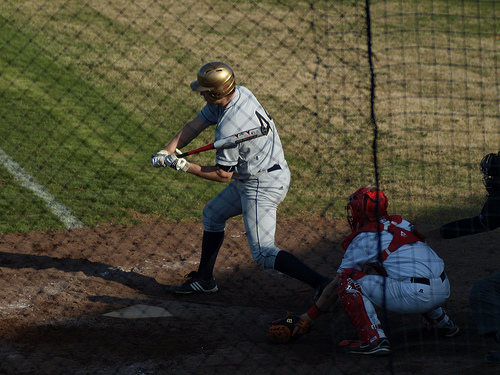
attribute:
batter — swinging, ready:
[172, 55, 330, 298]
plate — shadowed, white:
[105, 300, 178, 323]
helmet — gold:
[187, 63, 237, 95]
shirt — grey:
[208, 87, 282, 168]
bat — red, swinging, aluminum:
[173, 123, 273, 157]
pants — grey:
[207, 170, 288, 259]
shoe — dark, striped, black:
[169, 268, 221, 295]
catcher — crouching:
[313, 187, 460, 345]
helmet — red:
[358, 181, 385, 220]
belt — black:
[405, 271, 453, 285]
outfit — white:
[343, 229, 447, 317]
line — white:
[3, 141, 87, 233]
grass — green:
[4, 8, 495, 224]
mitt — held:
[264, 308, 307, 340]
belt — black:
[260, 161, 285, 174]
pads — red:
[338, 277, 380, 341]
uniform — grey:
[196, 95, 302, 262]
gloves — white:
[155, 146, 184, 171]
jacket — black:
[438, 199, 498, 233]